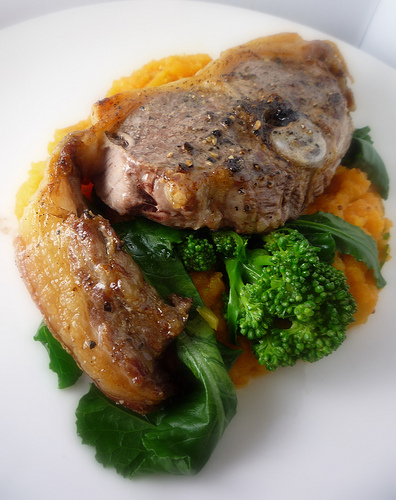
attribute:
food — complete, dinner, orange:
[5, 24, 395, 495]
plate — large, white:
[2, 3, 394, 499]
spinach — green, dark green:
[67, 408, 241, 485]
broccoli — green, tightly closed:
[133, 230, 357, 364]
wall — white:
[338, 0, 392, 40]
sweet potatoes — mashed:
[328, 172, 394, 316]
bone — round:
[259, 111, 334, 176]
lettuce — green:
[168, 325, 245, 476]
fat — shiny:
[12, 212, 185, 422]